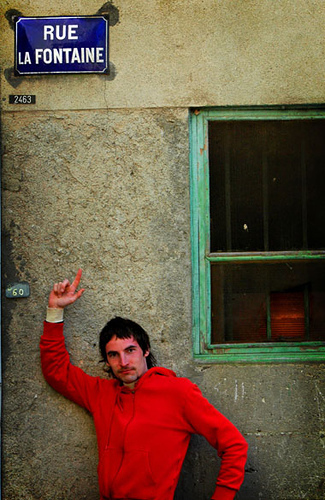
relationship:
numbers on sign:
[13, 93, 33, 102] [9, 91, 38, 106]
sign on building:
[12, 12, 111, 76] [1, 1, 314, 498]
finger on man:
[68, 265, 85, 291] [38, 267, 248, 499]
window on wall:
[205, 114, 325, 253] [1, 1, 314, 497]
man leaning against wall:
[38, 267, 248, 499] [1, 1, 314, 497]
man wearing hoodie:
[38, 267, 248, 499] [38, 319, 249, 499]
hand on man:
[46, 265, 85, 306] [38, 267, 248, 499]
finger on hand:
[68, 265, 85, 291] [46, 265, 85, 306]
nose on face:
[116, 348, 128, 367] [102, 333, 148, 383]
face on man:
[102, 333, 148, 383] [38, 267, 248, 499]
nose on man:
[116, 348, 128, 367] [38, 267, 248, 499]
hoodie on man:
[38, 319, 249, 499] [38, 267, 248, 499]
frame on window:
[189, 105, 315, 364] [189, 106, 315, 363]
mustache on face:
[114, 362, 138, 376] [104, 331, 147, 380]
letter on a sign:
[41, 23, 55, 41] [12, 12, 111, 76]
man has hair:
[38, 267, 248, 499] [97, 314, 153, 375]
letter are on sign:
[41, 23, 57, 43] [16, 17, 110, 77]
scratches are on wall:
[225, 374, 248, 404] [1, 1, 314, 497]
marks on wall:
[229, 377, 246, 404] [1, 1, 314, 497]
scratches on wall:
[268, 432, 322, 495] [1, 1, 314, 497]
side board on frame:
[187, 108, 210, 365] [189, 105, 325, 369]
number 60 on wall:
[7, 282, 28, 299] [13, 131, 164, 240]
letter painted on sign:
[55, 24, 66, 41] [12, 12, 111, 76]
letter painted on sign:
[17, 52, 24, 65] [12, 12, 111, 76]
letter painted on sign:
[24, 51, 32, 65] [12, 12, 111, 76]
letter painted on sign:
[41, 48, 51, 63] [12, 12, 111, 76]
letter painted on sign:
[52, 46, 62, 64] [12, 12, 111, 76]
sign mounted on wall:
[12, 12, 111, 76] [1, 1, 314, 497]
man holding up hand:
[38, 267, 248, 499] [46, 265, 85, 306]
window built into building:
[189, 106, 315, 363] [1, 1, 314, 498]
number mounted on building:
[11, 287, 24, 297] [1, 1, 314, 498]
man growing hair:
[38, 267, 248, 499] [97, 314, 153, 375]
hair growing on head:
[97, 314, 153, 375] [98, 314, 149, 381]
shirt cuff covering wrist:
[44, 306, 64, 324] [45, 304, 63, 320]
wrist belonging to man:
[45, 304, 63, 320] [38, 267, 248, 499]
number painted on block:
[11, 287, 18, 296] [4, 282, 30, 299]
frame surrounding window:
[189, 105, 315, 364] [208, 119, 314, 343]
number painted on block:
[13, 94, 31, 102] [7, 93, 35, 104]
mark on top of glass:
[237, 216, 254, 233] [212, 117, 316, 250]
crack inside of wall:
[249, 421, 324, 442] [162, 19, 323, 498]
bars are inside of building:
[219, 134, 304, 334] [1, 1, 314, 498]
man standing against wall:
[38, 267, 250, 499] [1, 1, 314, 497]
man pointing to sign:
[38, 267, 250, 499] [8, 9, 112, 81]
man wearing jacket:
[38, 267, 250, 499] [38, 371, 243, 490]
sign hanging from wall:
[12, 12, 111, 82] [6, 4, 315, 327]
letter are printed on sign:
[41, 23, 57, 43] [10, 11, 119, 83]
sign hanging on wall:
[4, 88, 35, 107] [10, 4, 177, 281]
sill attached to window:
[193, 340, 324, 364] [178, 99, 319, 367]